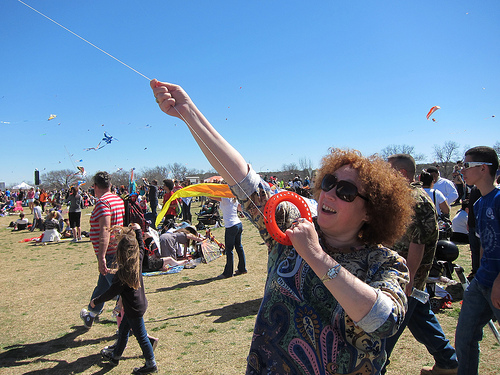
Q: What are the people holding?
A: Kites.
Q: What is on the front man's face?
A: Sunglasses.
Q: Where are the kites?
A: In the sky.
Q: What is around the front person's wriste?
A: A watch.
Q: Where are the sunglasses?
A: On the front person's face.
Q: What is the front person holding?
A: A string.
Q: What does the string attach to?
A: A kite.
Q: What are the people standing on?
A: Grass.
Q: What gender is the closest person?
A: Female.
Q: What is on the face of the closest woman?
A: Sunglasses.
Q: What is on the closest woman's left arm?
A: A watch.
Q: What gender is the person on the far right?
A: Male.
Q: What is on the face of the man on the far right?
A: White sunglasses.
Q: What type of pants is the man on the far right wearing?
A: Jeans.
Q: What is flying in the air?
A: Kites.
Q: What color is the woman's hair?
A: Red.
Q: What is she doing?
A: Flying a kite.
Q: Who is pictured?
A: A group of people flying kites.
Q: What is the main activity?
A: Kite flying.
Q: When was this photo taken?
A: During the day.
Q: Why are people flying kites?
A: Because it is fun.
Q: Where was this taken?
A: In a field.